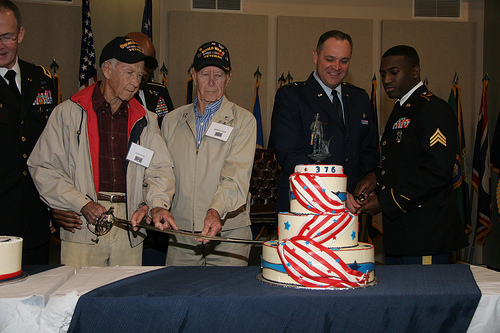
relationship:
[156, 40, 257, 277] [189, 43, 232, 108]
man has head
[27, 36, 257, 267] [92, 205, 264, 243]
men holding sword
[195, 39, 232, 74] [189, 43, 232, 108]
cap on head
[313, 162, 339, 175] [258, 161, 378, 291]
number on cake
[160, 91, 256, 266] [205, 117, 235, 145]
uniform with badge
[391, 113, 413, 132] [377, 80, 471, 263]
medals on uniform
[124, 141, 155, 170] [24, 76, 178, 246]
tag on jacket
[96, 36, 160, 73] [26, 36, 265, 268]
hat on men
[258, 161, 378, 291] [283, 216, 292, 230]
cake has star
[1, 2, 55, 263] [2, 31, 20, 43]
man wearing glasses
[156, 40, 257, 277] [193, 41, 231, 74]
man wearing cap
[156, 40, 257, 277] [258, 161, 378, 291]
man near cake